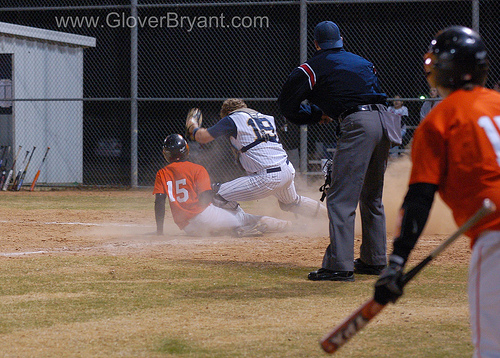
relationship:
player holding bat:
[370, 21, 497, 354] [313, 198, 498, 356]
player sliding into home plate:
[152, 132, 303, 239] [222, 233, 281, 238]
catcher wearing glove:
[182, 94, 332, 240] [182, 108, 206, 140]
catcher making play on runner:
[182, 94, 332, 240] [156, 133, 279, 231]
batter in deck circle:
[287, 229, 397, 333] [403, 304, 467, 346]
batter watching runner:
[287, 229, 397, 333] [156, 141, 218, 231]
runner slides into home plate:
[156, 141, 218, 231] [222, 233, 281, 238]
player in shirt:
[370, 21, 497, 354] [405, 82, 497, 250]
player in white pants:
[370, 21, 497, 354] [468, 227, 499, 356]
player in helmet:
[370, 21, 497, 354] [418, 22, 493, 92]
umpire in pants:
[274, 20, 405, 282] [316, 102, 395, 270]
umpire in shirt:
[274, 20, 405, 282] [275, 49, 381, 126]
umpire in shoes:
[274, 20, 405, 282] [350, 256, 384, 275]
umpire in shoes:
[274, 20, 405, 282] [305, 265, 358, 283]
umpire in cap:
[274, 20, 405, 282] [313, 14, 344, 51]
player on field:
[152, 132, 303, 239] [2, 185, 474, 355]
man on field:
[148, 126, 298, 275] [2, 185, 474, 355]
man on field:
[148, 130, 304, 241] [14, 110, 441, 356]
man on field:
[372, 25, 497, 354] [2, 185, 474, 355]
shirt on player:
[405, 82, 497, 250] [370, 21, 497, 354]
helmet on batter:
[418, 22, 493, 92] [322, 25, 499, 356]